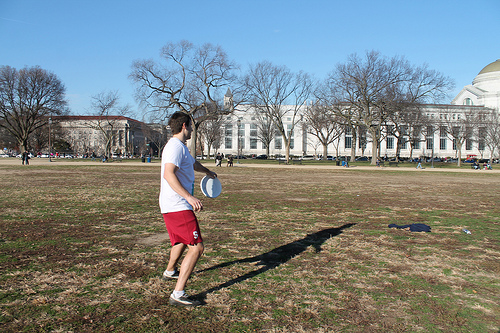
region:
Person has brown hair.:
[160, 102, 202, 144]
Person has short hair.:
[146, 112, 208, 149]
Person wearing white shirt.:
[142, 128, 197, 199]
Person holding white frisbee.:
[196, 157, 229, 221]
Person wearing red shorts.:
[152, 210, 239, 265]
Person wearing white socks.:
[156, 245, 211, 332]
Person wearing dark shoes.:
[163, 279, 192, 306]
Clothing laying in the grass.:
[385, 208, 433, 260]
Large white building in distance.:
[316, 46, 498, 161]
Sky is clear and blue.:
[263, 14, 393, 54]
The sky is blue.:
[3, 4, 489, 93]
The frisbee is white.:
[203, 173, 224, 197]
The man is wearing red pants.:
[154, 206, 204, 247]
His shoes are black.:
[155, 263, 202, 313]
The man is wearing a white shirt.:
[150, 136, 206, 209]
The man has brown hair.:
[160, 103, 197, 142]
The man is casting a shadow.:
[192, 215, 372, 293]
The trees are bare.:
[3, 41, 496, 162]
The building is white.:
[203, 92, 498, 162]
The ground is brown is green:
[10, 165, 499, 329]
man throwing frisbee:
[132, 97, 315, 314]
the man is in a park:
[36, 109, 483, 318]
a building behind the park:
[202, 39, 494, 157]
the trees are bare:
[7, 24, 497, 186]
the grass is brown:
[24, 153, 477, 320]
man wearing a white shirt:
[137, 104, 207, 218]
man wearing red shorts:
[146, 199, 244, 259]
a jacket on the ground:
[379, 206, 441, 255]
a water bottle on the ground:
[455, 215, 483, 257]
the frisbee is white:
[190, 164, 233, 223]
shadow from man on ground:
[202, 214, 366, 306]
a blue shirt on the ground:
[386, 207, 436, 243]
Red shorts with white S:
[157, 198, 232, 268]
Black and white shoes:
[162, 281, 232, 316]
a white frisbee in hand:
[197, 168, 231, 210]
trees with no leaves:
[123, 48, 456, 190]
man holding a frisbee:
[138, 96, 251, 323]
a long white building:
[187, 76, 499, 176]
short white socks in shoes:
[170, 284, 190, 307]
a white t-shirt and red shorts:
[147, 140, 213, 252]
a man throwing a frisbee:
[113, 96, 263, 309]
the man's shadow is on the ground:
[166, 125, 367, 315]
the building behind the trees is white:
[121, 35, 496, 187]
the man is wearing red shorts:
[143, 102, 238, 310]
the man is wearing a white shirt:
[135, 95, 232, 317]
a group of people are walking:
[204, 146, 251, 171]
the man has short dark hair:
[162, 107, 200, 150]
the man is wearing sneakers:
[139, 103, 231, 315]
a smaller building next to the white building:
[2, 85, 494, 167]